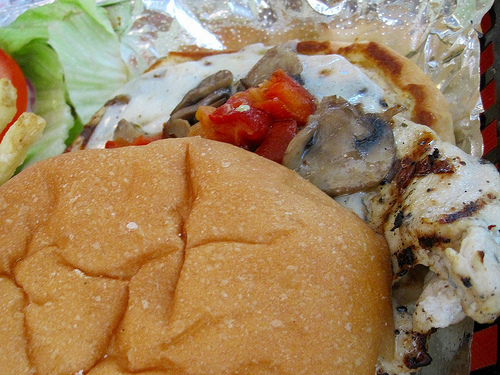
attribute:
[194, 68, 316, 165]
pepper — cooked red 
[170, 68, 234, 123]
mushroom — slice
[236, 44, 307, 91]
mushroom — slice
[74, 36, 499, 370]
cheese — melted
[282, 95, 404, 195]
mushroom — slice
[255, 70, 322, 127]
tomato — red 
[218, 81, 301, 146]
tomatoes — pile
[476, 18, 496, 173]
basket — black 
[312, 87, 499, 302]
meat — cooked , piece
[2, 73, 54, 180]
french fries — ends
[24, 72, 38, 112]
onion — purple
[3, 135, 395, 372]
bun — brown 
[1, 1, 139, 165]
lettuce — green 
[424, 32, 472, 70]
pizza —  plain cheese 